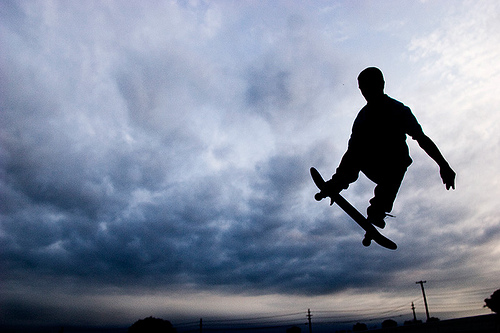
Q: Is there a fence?
A: No, there are no fences.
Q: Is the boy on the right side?
A: Yes, the boy is on the right of the image.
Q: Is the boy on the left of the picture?
A: No, the boy is on the right of the image.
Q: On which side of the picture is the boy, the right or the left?
A: The boy is on the right of the image.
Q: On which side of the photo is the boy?
A: The boy is on the right of the image.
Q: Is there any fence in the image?
A: No, there are no fences.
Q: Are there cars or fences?
A: No, there are no fences or cars.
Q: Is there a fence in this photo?
A: No, there are no fences.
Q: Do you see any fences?
A: No, there are no fences.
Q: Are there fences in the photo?
A: No, there are no fences.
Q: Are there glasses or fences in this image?
A: No, there are no fences or glasses.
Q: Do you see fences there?
A: No, there are no fences.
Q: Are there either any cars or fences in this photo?
A: No, there are no fences or cars.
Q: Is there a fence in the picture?
A: No, there are no fences.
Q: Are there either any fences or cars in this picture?
A: No, there are no fences or cars.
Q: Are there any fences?
A: No, there are no fences.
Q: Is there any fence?
A: No, there are no fences.